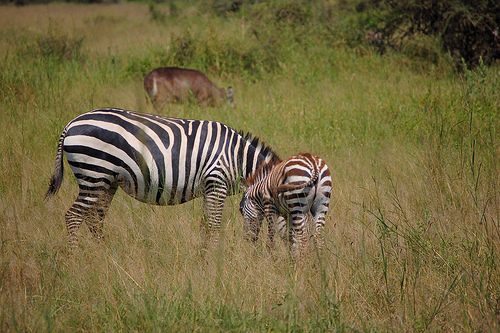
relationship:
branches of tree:
[364, 22, 418, 34] [367, 1, 491, 85]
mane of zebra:
[229, 114, 264, 147] [269, 168, 315, 242]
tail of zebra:
[45, 134, 72, 190] [269, 168, 315, 242]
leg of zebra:
[49, 204, 102, 239] [269, 168, 315, 242]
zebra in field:
[269, 168, 315, 242] [256, 37, 308, 68]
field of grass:
[256, 37, 308, 68] [6, 59, 50, 101]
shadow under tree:
[306, 15, 401, 79] [367, 1, 491, 85]